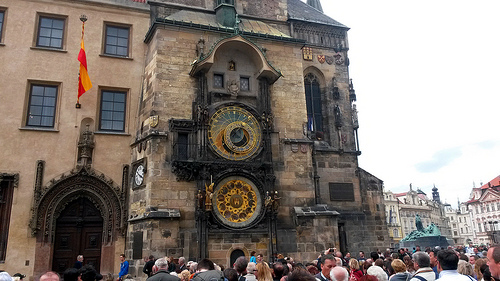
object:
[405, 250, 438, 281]
people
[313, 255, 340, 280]
people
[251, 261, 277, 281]
people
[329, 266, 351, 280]
people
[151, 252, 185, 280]
people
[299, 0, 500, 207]
cloudy sky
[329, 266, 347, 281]
bald head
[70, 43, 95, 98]
flags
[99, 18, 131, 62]
multi-pane window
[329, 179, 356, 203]
plaque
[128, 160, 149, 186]
clock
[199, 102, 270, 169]
clock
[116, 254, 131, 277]
blue shirt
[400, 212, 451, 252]
statue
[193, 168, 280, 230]
clock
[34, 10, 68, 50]
window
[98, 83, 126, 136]
window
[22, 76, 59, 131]
window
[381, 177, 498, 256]
building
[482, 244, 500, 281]
people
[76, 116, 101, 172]
statue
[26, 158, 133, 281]
arched doorway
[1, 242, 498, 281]
crowd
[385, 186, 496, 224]
distance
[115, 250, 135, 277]
man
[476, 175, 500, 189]
roof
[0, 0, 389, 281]
building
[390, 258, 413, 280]
person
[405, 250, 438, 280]
person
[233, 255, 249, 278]
person